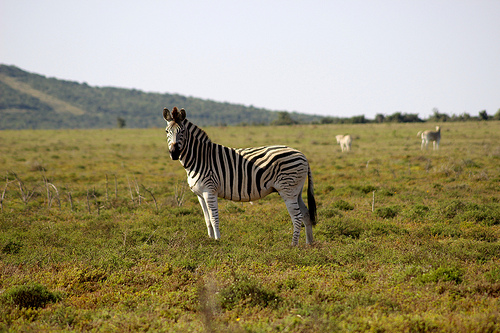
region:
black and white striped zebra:
[152, 97, 328, 260]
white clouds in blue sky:
[126, 22, 171, 72]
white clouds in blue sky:
[184, 19, 217, 65]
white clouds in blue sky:
[254, 37, 283, 79]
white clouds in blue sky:
[282, 13, 324, 85]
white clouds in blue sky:
[428, 27, 473, 97]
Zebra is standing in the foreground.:
[150, 95, 321, 255]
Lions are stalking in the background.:
[325, 115, 465, 165]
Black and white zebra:
[140, 96, 325, 251]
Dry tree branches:
[0, 175, 175, 215]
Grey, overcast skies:
[0, 7, 498, 115]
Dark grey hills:
[0, 52, 366, 123]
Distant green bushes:
[250, 98, 497, 129]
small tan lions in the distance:
[330, 125, 458, 161]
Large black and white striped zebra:
[152, 104, 322, 256]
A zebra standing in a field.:
[145, 90, 331, 267]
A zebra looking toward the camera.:
[155, 91, 330, 253]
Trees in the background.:
[273, 103, 499, 128]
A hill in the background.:
[3, 52, 329, 132]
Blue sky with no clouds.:
[20, 5, 471, 66]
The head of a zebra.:
[151, 100, 191, 165]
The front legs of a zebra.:
[181, 176, 226, 246]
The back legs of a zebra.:
[275, 182, 315, 248]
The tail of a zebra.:
[300, 155, 322, 236]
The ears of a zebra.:
[158, 101, 193, 127]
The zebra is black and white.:
[161, 100, 328, 247]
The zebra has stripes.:
[164, 100, 322, 247]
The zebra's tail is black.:
[308, 163, 318, 225]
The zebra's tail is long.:
[308, 166, 320, 228]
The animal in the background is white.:
[337, 130, 352, 152]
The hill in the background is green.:
[83, 86, 120, 117]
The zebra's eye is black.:
[180, 128, 186, 137]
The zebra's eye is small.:
[177, 126, 188, 138]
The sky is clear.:
[316, 53, 394, 91]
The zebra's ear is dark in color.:
[157, 106, 173, 119]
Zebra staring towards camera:
[155, 102, 331, 257]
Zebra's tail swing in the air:
[300, 157, 320, 227]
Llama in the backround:
[415, 121, 445, 148]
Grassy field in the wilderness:
[0, 117, 497, 327]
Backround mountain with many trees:
[0, 61, 335, 121]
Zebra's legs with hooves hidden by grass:
[190, 196, 320, 251]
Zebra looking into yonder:
[155, 105, 320, 255]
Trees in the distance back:
[275, 108, 497, 120]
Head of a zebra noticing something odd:
[160, 103, 188, 162]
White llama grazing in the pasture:
[332, 132, 360, 154]